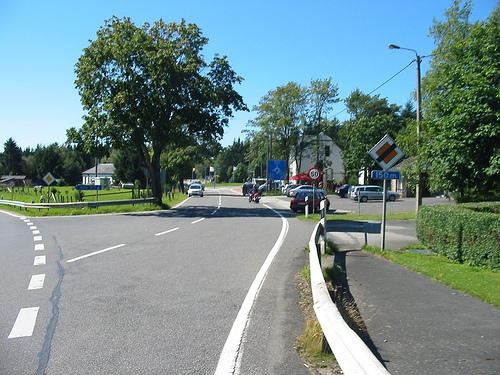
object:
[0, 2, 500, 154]
sky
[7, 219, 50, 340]
line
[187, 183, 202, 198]
car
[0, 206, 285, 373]
road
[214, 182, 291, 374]
lines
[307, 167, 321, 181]
number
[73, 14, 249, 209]
tree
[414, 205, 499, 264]
bushes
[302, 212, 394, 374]
barricade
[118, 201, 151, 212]
grass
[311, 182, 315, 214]
pole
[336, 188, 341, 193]
lamp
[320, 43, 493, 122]
lines